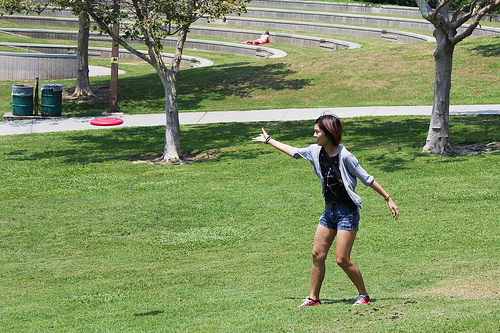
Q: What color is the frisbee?
A: Red.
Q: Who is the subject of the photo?
A: The girl.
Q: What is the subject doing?
A: Throwing a frisbee.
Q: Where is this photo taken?
A: In the park.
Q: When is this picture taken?
A: In the daytime.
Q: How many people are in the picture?
A: Two.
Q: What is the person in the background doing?
A: Lying down.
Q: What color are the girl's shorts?
A: Blue.